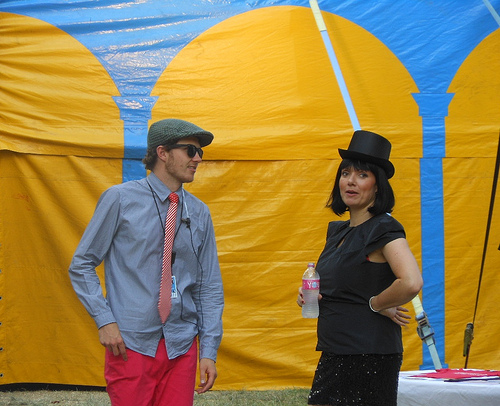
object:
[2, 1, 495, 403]
picture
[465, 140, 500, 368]
strap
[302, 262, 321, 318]
water bottle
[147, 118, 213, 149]
hat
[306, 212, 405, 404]
clothes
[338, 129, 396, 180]
hat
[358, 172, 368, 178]
eye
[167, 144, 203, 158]
glasses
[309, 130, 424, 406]
human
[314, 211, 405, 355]
shirt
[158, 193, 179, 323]
tie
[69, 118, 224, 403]
human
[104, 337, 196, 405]
pants